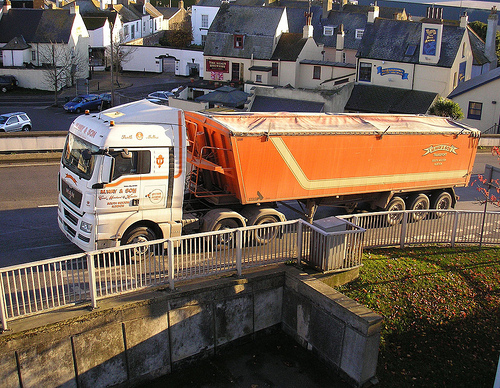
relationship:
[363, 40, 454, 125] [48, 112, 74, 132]
business by road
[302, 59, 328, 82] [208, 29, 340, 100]
window of building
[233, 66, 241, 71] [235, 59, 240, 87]
window on door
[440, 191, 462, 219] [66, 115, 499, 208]
wheel of truck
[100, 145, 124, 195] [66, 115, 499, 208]
mirror of truck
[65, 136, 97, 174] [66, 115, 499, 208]
window of truck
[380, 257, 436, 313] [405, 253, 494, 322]
grass on ground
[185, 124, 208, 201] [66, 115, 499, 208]
ladder of truck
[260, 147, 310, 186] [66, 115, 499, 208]
white on truck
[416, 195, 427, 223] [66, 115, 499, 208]
wheel of truck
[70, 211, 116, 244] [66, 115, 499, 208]
headlight of truck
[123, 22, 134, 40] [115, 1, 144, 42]
window on building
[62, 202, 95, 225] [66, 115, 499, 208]
grill of truck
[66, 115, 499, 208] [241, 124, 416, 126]
truck to haul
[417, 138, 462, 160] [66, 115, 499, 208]
logo on truck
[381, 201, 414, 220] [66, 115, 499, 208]
tire on truck